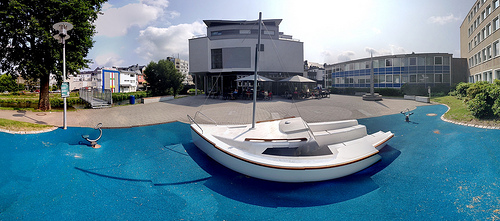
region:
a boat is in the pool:
[173, 12, 403, 182]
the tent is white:
[280, 70, 314, 90]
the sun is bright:
[302, 3, 384, 35]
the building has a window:
[405, 55, 420, 65]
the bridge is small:
[75, 84, 117, 109]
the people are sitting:
[287, 86, 327, 98]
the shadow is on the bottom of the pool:
[244, 183, 345, 209]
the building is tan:
[463, 2, 498, 78]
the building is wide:
[322, 47, 467, 94]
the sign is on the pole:
[52, 79, 72, 98]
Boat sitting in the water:
[5, 5, 499, 218]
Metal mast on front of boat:
[251, 10, 263, 128]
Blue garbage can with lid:
[128, 95, 133, 104]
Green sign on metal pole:
[59, 82, 69, 97]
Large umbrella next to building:
[280, 73, 316, 83]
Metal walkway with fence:
[78, 84, 113, 109]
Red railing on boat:
[243, 135, 307, 141]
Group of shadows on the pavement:
[8, 106, 49, 125]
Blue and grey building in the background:
[323, 52, 468, 94]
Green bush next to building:
[458, 80, 499, 119]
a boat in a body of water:
[7, 105, 496, 218]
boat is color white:
[180, 100, 396, 186]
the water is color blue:
[5, 111, 496, 213]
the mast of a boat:
[244, 7, 275, 129]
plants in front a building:
[443, 5, 498, 121]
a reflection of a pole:
[70, 156, 203, 200]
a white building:
[174, 12, 324, 104]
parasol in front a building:
[236, 69, 321, 98]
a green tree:
[5, 4, 103, 113]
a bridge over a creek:
[74, 77, 118, 113]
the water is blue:
[385, 179, 438, 206]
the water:
[135, 184, 185, 219]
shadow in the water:
[268, 183, 323, 206]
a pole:
[53, 40, 78, 80]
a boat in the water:
[181, 110, 408, 177]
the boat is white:
[186, 108, 393, 183]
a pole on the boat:
[248, 18, 265, 137]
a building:
[381, 58, 452, 86]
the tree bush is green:
[466, 78, 499, 113]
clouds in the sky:
[113, 12, 191, 44]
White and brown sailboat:
[179, 5, 404, 186]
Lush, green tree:
[0, 1, 112, 116]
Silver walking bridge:
[74, 81, 115, 108]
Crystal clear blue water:
[3, 100, 499, 219]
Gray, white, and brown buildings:
[181, 0, 499, 99]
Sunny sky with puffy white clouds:
[1, 1, 498, 74]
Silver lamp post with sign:
[46, 18, 81, 129]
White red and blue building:
[96, 65, 140, 95]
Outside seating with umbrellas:
[231, 75, 333, 100]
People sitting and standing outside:
[226, 84, 336, 100]